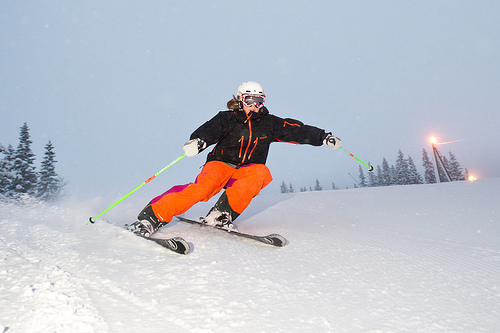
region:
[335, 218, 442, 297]
fresh snow on the ground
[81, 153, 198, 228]
lime green ski pole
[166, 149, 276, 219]
skier wearing orange pants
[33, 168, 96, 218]
snow splashing in the back ground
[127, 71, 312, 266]
skier moving down hill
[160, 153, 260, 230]
orange pants worn by skier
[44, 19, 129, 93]
white clouds in blue sky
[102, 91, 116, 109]
white clouds in blue sky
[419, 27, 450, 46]
white clouds in blue sky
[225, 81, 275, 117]
A person wearing a white helmet.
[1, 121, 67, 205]
A forest of trees.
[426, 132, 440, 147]
A light on top of a tree.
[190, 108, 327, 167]
A black and red shirt.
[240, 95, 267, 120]
A woman wearing snow goggles.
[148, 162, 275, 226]
A pair of neon orange pants.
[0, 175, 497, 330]
A snow covered hillside.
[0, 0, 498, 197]
A hazy blue sky.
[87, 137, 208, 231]
A ski pole in the snow.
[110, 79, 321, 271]
skier on hill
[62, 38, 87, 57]
white clouds in blue sky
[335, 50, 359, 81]
white clouds in blue sky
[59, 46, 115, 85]
white clouds in blue sky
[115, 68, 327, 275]
skier moving quickly down hill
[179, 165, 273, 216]
orange pants worn by man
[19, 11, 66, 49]
white clouds in blue sky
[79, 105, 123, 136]
white clouds in blue sky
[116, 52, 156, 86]
white clouds in blue sky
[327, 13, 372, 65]
white clouds in blue sky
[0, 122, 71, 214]
A tree filled forest.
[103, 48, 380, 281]
a person on skis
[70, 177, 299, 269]
a pair of skis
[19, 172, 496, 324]
snow on the ground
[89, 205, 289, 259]
a pair of skis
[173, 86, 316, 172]
a black and orange jacket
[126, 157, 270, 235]
a pair of orange pants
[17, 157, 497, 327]
snow on the ground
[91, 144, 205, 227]
ski pole is green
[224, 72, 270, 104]
a white ski helmet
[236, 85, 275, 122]
a pair of goggles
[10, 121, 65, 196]
snow on the trees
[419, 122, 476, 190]
lights on the side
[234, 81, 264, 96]
the helmet is white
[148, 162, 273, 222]
the pants are orange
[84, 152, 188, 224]
the ski pole is green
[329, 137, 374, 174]
the ski pole is green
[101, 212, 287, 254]
the skis are black and gray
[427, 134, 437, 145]
the light is bright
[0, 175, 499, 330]
the snow is white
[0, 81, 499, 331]
the person skiing on the snow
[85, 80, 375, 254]
the person is dressed for skiing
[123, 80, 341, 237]
person skiing in orange pants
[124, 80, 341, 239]
person skiing in black jacket